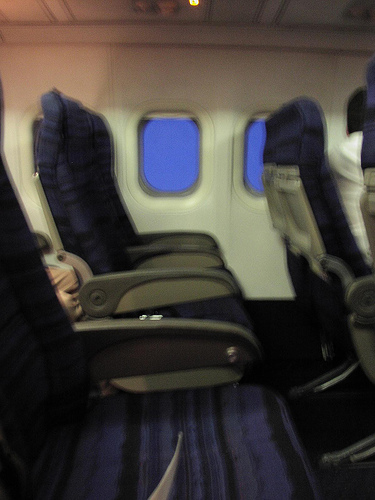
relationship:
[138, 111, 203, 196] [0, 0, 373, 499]
window on airplane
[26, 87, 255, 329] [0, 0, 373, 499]
seat on airplane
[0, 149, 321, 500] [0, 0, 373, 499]
seat on airplane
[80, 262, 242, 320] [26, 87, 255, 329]
armrest of seat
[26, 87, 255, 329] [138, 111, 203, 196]
seat by window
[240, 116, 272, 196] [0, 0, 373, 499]
window on airplane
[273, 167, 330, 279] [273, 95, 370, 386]
tray table on back of seat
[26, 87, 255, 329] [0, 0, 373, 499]
seat inside of airplane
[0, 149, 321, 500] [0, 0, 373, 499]
seat inside of airplane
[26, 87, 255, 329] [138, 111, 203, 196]
seat next to window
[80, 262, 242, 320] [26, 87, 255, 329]
armrest attached to seat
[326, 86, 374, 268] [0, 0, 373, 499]
passenger on airplane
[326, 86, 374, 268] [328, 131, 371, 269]
passenger wearing shirt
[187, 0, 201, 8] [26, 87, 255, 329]
light above seat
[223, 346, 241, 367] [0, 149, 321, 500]
button on seat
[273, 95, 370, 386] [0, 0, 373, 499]
seat on airplane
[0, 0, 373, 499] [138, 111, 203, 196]
airplane has window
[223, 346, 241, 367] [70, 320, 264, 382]
button on armrest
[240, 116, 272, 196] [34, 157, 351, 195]
window are in a row